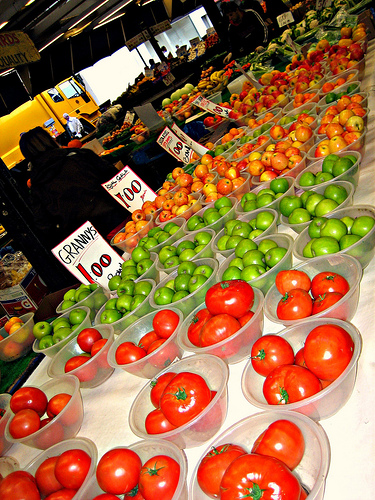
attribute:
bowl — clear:
[279, 181, 352, 233]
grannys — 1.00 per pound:
[31, 151, 372, 355]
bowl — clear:
[308, 133, 366, 165]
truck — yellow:
[0, 69, 102, 170]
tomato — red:
[163, 374, 212, 426]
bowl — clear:
[289, 206, 374, 275]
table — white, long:
[8, 40, 375, 494]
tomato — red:
[307, 329, 358, 381]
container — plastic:
[6, 376, 85, 456]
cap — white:
[61, 113, 67, 119]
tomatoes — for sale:
[0, 270, 355, 498]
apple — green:
[276, 197, 303, 218]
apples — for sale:
[115, 22, 367, 250]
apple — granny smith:
[153, 286, 177, 306]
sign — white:
[154, 125, 197, 169]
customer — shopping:
[18, 127, 128, 256]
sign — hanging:
[0, 30, 43, 72]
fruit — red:
[4, 270, 355, 500]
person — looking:
[218, 1, 274, 61]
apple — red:
[193, 164, 208, 180]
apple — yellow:
[247, 151, 264, 163]